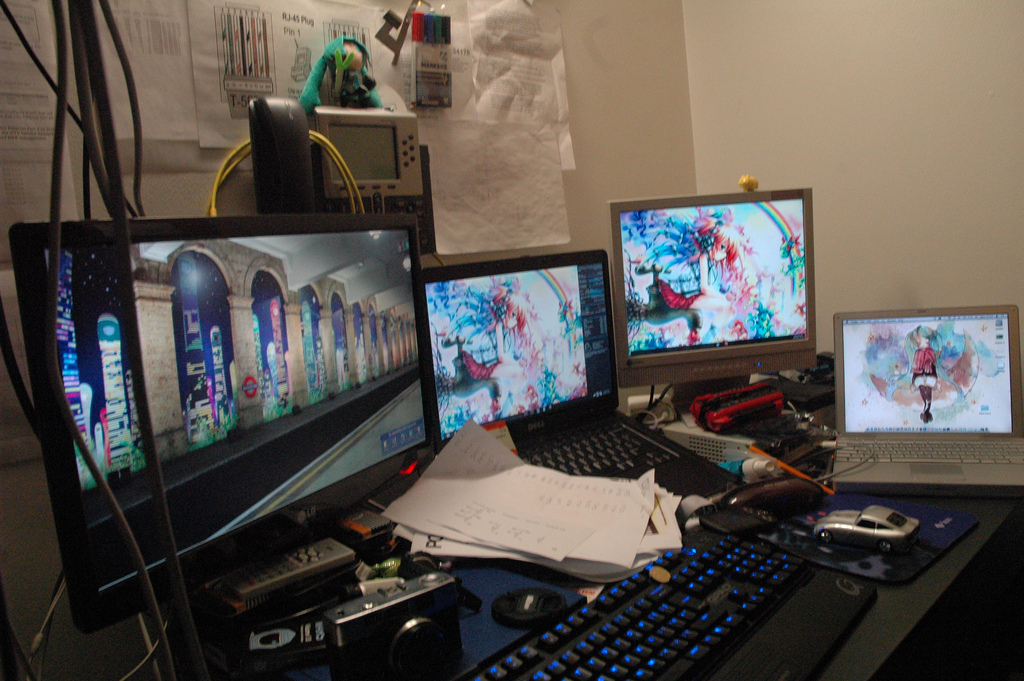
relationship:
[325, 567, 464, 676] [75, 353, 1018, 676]
camera on desk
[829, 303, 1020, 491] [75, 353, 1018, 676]
laptop on desk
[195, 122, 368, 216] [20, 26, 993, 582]
cord hanging on wall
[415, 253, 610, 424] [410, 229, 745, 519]
screen on laptop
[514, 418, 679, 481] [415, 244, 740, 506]
keyboard on laptop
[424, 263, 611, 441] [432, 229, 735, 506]
screen on laptop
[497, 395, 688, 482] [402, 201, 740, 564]
keyboard on laptop